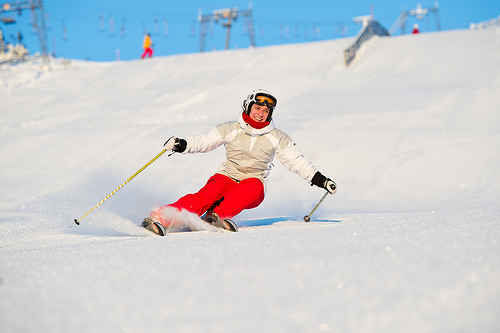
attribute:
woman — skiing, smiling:
[141, 91, 337, 237]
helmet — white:
[242, 92, 277, 123]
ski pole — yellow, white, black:
[70, 149, 169, 225]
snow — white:
[0, 30, 499, 332]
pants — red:
[153, 173, 264, 223]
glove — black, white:
[311, 170, 337, 196]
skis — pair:
[140, 217, 239, 234]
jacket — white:
[183, 117, 319, 181]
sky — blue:
[0, 0, 499, 62]